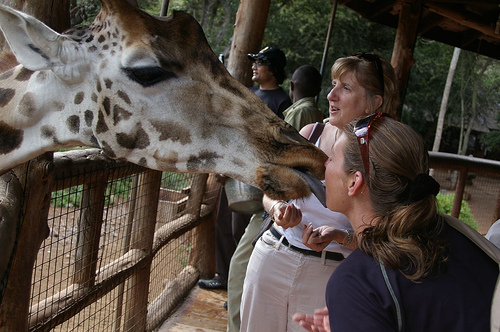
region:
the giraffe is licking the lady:
[31, 9, 427, 281]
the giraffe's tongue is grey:
[210, 114, 387, 254]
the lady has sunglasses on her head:
[316, 92, 394, 228]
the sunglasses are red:
[344, 117, 394, 185]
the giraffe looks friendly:
[73, 2, 358, 238]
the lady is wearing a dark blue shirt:
[338, 214, 498, 329]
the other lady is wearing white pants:
[243, 238, 353, 330]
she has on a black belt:
[264, 218, 354, 270]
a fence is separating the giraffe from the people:
[35, 187, 184, 327]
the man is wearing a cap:
[244, 45, 311, 96]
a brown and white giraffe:
[0, 0, 330, 204]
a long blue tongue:
[293, 165, 330, 210]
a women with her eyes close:
[323, 112, 498, 329]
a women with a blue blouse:
[327, 209, 497, 330]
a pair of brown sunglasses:
[349, 108, 393, 192]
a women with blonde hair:
[340, 107, 440, 277]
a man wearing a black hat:
[245, 42, 290, 78]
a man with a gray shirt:
[277, 60, 322, 130]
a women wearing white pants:
[237, 225, 347, 327]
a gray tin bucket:
[220, 175, 261, 216]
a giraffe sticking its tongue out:
[46, 18, 349, 228]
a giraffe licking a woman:
[68, 35, 435, 253]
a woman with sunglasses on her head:
[306, 83, 457, 286]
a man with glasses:
[247, 43, 315, 100]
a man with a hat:
[231, 35, 313, 109]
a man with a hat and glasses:
[236, 34, 316, 141]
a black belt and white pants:
[243, 215, 388, 301]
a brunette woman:
[314, 110, 453, 284]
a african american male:
[265, 57, 334, 137]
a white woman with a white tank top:
[291, 54, 441, 169]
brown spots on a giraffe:
[22, 79, 109, 136]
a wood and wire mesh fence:
[43, 203, 63, 273]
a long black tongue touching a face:
[297, 171, 322, 200]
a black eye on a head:
[123, 46, 177, 91]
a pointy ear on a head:
[10, 4, 65, 67]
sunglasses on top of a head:
[346, 109, 383, 166]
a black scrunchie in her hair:
[398, 162, 442, 204]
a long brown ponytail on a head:
[397, 165, 419, 263]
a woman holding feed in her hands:
[276, 58, 344, 318]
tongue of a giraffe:
[311, 180, 325, 200]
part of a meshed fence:
[101, 221, 139, 268]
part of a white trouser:
[260, 265, 294, 308]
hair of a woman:
[386, 218, 423, 255]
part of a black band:
[416, 174, 431, 194]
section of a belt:
[317, 250, 332, 263]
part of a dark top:
[428, 286, 458, 314]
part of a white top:
[303, 195, 324, 222]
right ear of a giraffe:
[0, 15, 80, 87]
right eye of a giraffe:
[123, 53, 182, 81]